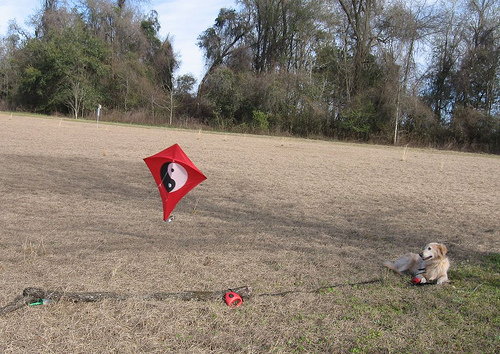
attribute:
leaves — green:
[300, 82, 318, 98]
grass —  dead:
[255, 162, 407, 297]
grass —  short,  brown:
[0, 109, 498, 352]